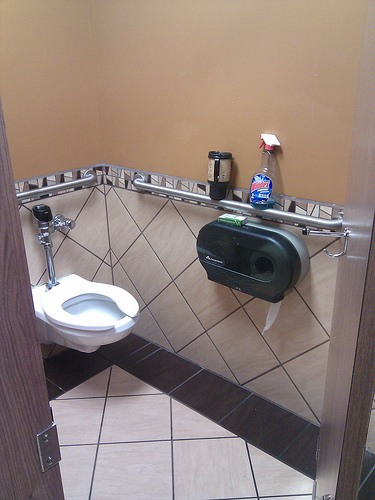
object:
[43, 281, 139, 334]
toilet seat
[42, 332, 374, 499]
floor tiles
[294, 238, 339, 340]
tile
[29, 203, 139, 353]
flush toilet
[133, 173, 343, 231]
hand rail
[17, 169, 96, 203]
hand rail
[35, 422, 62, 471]
door hinge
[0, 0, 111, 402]
wall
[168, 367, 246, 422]
tile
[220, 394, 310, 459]
tile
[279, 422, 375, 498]
tile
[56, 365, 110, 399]
tile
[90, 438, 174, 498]
tile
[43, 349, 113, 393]
tile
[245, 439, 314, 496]
tile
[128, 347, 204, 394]
tile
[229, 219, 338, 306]
tile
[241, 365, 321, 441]
tile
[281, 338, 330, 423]
tile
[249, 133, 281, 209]
cleaner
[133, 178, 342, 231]
bar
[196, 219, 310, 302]
cover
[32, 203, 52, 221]
button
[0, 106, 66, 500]
door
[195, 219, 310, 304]
toilet-paper holder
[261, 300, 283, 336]
toilet paper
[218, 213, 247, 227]
pack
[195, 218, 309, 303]
dispenser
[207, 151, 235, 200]
cup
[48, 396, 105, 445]
tile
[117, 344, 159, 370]
tile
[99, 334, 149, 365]
tile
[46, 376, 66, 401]
tile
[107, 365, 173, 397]
tile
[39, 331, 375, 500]
floor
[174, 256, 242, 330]
tile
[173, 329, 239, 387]
tile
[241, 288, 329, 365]
tile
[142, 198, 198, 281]
tile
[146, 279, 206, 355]
tile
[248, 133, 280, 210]
bottle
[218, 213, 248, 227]
carton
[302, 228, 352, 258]
rack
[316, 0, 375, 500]
door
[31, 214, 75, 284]
pipe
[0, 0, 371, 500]
toilet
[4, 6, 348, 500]
stall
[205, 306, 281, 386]
tile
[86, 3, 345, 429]
wall